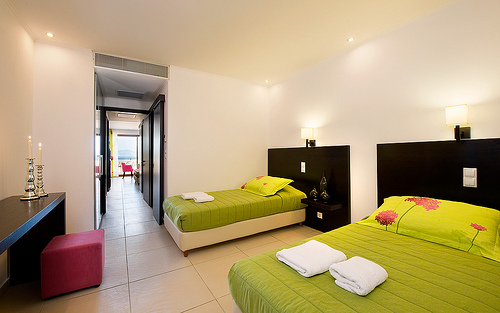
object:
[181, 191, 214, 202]
towel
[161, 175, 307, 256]
bed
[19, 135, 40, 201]
candle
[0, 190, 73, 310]
desk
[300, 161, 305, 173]
plug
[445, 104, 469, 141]
light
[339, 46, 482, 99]
wall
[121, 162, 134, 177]
chair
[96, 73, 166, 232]
hallway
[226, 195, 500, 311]
bed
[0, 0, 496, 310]
room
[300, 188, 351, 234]
table